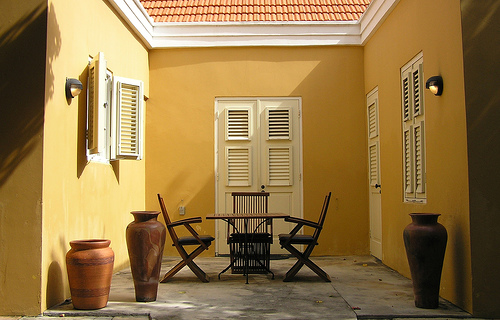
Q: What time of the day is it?
A: Daytime.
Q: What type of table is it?
A: A dining table.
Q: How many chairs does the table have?
A: Three.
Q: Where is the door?
A: Behind the chair.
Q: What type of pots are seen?
A: Vases.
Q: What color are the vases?
A: Brown.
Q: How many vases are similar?
A: Two.